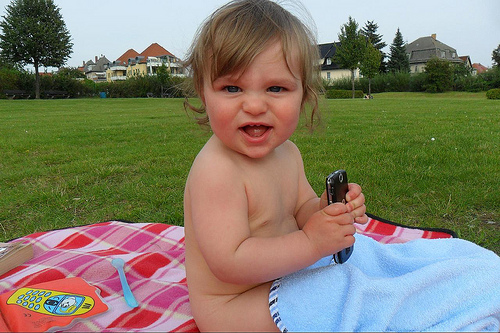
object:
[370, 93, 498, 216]
grass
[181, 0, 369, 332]
baby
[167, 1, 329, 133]
hair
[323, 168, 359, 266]
phone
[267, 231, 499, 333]
towel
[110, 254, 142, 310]
spoon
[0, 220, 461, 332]
blanket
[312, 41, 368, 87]
house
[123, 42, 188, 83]
house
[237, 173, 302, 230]
chest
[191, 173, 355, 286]
arm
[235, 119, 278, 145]
mouth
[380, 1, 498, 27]
sky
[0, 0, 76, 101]
tree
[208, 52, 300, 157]
face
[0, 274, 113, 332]
toy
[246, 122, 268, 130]
teeth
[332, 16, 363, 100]
tree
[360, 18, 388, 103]
tree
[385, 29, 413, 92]
tree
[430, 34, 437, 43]
chimney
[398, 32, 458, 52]
roof